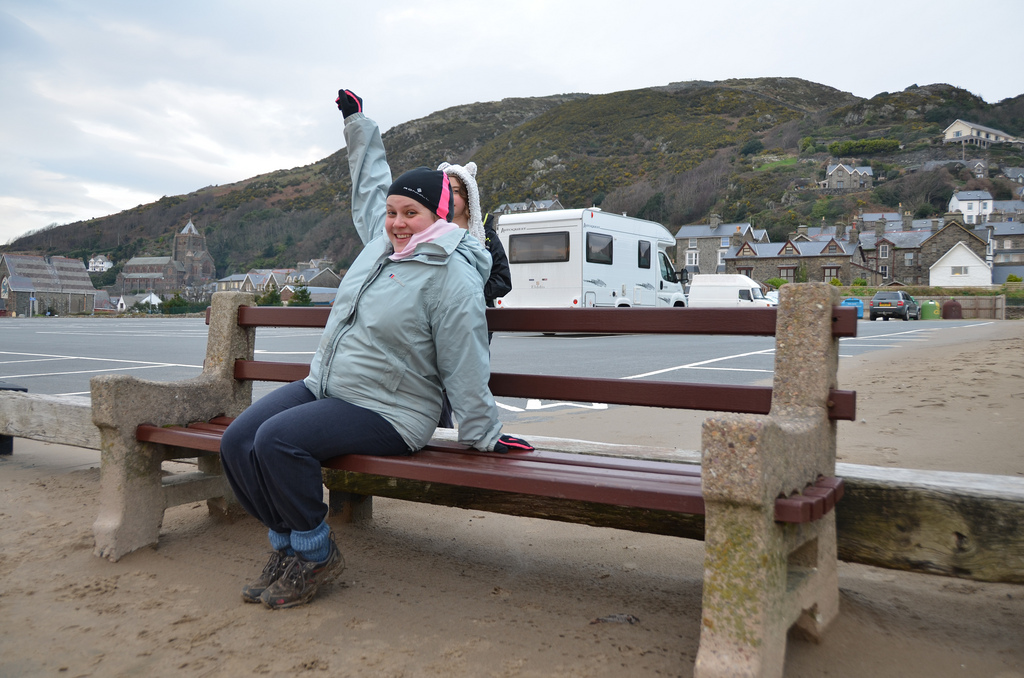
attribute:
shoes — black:
[251, 520, 356, 607]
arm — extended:
[294, 82, 411, 248]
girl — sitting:
[207, 90, 528, 606]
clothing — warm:
[218, 220, 528, 603]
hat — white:
[433, 155, 492, 253]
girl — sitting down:
[130, 133, 644, 573]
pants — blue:
[198, 372, 396, 524]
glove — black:
[309, 68, 385, 158]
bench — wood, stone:
[436, 171, 819, 555]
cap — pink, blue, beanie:
[378, 164, 462, 222]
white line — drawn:
[27, 315, 146, 379]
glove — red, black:
[324, 76, 414, 127]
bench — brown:
[88, 282, 856, 675]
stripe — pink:
[432, 159, 453, 229]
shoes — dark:
[251, 525, 359, 612]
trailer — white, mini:
[488, 199, 689, 307]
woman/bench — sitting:
[89, 168, 867, 659]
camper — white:
[490, 197, 702, 316]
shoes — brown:
[219, 528, 380, 634]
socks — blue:
[243, 512, 356, 562]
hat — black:
[380, 163, 465, 230]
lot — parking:
[8, 294, 987, 433]